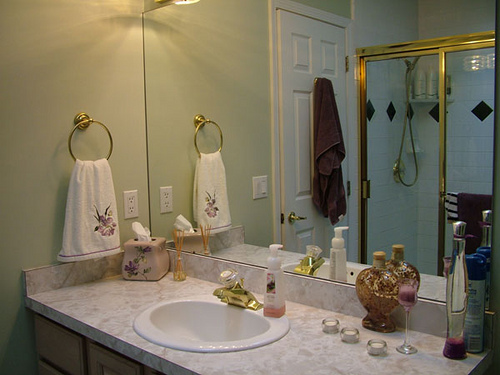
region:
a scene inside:
[6, 13, 497, 365]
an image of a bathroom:
[5, 6, 498, 349]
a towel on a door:
[291, 63, 377, 237]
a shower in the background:
[346, 31, 498, 293]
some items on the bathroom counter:
[100, 206, 499, 371]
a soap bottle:
[252, 228, 295, 327]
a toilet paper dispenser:
[116, 206, 193, 303]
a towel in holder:
[56, 161, 121, 267]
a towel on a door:
[313, 77, 343, 220]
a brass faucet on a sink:
[206, 265, 261, 314]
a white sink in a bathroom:
[133, 290, 293, 352]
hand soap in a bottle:
[262, 242, 287, 319]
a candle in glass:
[361, 337, 391, 356]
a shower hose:
[391, 69, 423, 191]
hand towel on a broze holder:
[44, 94, 128, 274]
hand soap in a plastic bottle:
[253, 241, 298, 324]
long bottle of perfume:
[438, 209, 469, 363]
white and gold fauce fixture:
[198, 264, 267, 324]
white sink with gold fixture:
[141, 260, 296, 357]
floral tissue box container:
[113, 216, 163, 292]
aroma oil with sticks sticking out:
[165, 211, 190, 289]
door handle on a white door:
[275, 201, 313, 235]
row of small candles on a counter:
[313, 317, 387, 361]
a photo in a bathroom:
[21, 28, 486, 374]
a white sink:
[122, 257, 300, 363]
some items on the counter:
[24, 197, 487, 374]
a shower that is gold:
[345, 38, 498, 288]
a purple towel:
[300, 68, 365, 231]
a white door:
[273, 18, 370, 260]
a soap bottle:
[249, 230, 299, 332]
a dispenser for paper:
[111, 215, 181, 289]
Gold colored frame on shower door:
[356, 28, 498, 267]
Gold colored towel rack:
[66, 112, 120, 169]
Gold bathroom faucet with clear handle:
[211, 265, 262, 312]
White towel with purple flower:
[55, 155, 124, 262]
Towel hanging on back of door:
[310, 73, 349, 225]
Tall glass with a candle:
[395, 282, 419, 357]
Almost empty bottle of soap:
[262, 241, 287, 317]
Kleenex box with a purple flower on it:
[119, 222, 174, 282]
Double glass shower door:
[366, 41, 498, 270]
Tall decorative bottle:
[441, 218, 473, 359]